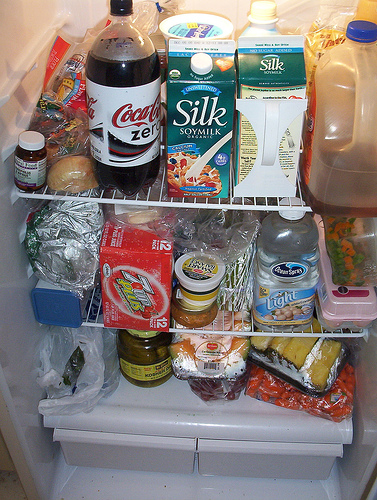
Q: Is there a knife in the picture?
A: No, there are no knives.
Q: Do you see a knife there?
A: No, there are no knives.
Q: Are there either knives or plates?
A: No, there are no knives or plates.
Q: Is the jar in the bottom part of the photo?
A: Yes, the jar is in the bottom of the image.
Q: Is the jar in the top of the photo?
A: No, the jar is in the bottom of the image.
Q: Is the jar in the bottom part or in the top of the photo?
A: The jar is in the bottom of the image.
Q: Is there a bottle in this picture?
A: Yes, there is a bottle.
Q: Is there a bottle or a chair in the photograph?
A: Yes, there is a bottle.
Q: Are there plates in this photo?
A: No, there are no plates.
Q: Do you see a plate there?
A: No, there are no plates.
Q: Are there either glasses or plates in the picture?
A: No, there are no plates or glasses.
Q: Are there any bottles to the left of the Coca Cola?
A: Yes, there is a bottle to the left of the Coca Cola.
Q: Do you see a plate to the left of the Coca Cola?
A: No, there is a bottle to the left of the Coca Cola.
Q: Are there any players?
A: No, there are no players.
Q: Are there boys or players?
A: No, there are no players or boys.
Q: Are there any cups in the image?
A: No, there are no cups.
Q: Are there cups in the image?
A: No, there are no cups.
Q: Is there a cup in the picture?
A: No, there are no cups.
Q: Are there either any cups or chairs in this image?
A: No, there are no cups or chairs.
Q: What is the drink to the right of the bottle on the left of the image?
A: The drink is Coke.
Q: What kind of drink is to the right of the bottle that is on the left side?
A: The drink is Coke.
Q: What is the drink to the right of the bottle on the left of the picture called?
A: The drink is Coke.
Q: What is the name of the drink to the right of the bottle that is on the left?
A: The drink is Coke.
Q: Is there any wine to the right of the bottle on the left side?
A: No, there is Coke to the right of the bottle.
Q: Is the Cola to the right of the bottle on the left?
A: Yes, the Cola is to the right of the bottle.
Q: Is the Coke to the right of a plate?
A: No, the Coke is to the right of the bottle.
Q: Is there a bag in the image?
A: Yes, there is a bag.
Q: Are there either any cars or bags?
A: Yes, there is a bag.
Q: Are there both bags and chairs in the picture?
A: No, there is a bag but no chairs.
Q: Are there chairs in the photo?
A: No, there are no chairs.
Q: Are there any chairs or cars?
A: No, there are no chairs or cars.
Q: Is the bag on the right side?
A: Yes, the bag is on the right of the image.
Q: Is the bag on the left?
A: No, the bag is on the right of the image.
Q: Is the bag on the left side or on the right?
A: The bag is on the right of the image.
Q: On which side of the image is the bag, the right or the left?
A: The bag is on the right of the image.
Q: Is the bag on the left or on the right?
A: The bag is on the right of the image.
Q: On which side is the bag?
A: The bag is on the right of the image.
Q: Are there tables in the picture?
A: No, there are no tables.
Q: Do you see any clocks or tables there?
A: No, there are no tables or clocks.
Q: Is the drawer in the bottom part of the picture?
A: Yes, the drawer is in the bottom of the image.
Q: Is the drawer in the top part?
A: No, the drawer is in the bottom of the image.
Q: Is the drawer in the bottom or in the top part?
A: The drawer is in the bottom of the image.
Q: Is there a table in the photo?
A: No, there are no tables.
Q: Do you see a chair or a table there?
A: No, there are no tables or chairs.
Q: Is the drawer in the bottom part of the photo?
A: Yes, the drawer is in the bottom of the image.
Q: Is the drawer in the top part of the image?
A: No, the drawer is in the bottom of the image.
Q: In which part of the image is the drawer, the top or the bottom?
A: The drawer is in the bottom of the image.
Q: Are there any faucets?
A: No, there are no faucets.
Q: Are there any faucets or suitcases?
A: No, there are no faucets or suitcases.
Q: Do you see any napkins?
A: No, there are no napkins.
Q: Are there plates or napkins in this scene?
A: No, there are no napkins or plates.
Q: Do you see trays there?
A: No, there are no trays.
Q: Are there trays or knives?
A: No, there are no trays or knives.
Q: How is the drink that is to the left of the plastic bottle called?
A: The drink is juice.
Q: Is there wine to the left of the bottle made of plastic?
A: No, there is juice to the left of the bottle.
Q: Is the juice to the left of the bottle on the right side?
A: Yes, the juice is to the left of the bottle.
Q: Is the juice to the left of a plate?
A: No, the juice is to the left of the bottle.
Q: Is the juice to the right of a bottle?
A: No, the juice is to the left of a bottle.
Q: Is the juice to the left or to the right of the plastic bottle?
A: The juice is to the left of the bottle.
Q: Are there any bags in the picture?
A: Yes, there is a bag.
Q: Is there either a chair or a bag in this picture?
A: Yes, there is a bag.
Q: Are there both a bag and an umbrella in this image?
A: No, there is a bag but no umbrellas.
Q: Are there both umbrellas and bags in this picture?
A: No, there is a bag but no umbrellas.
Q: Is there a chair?
A: No, there are no chairs.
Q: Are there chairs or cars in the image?
A: No, there are no chairs or cars.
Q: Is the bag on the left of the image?
A: No, the bag is on the right of the image.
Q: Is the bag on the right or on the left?
A: The bag is on the right of the image.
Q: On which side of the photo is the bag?
A: The bag is on the right of the image.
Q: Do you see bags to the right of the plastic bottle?
A: Yes, there is a bag to the right of the bottle.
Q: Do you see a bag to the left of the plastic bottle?
A: No, the bag is to the right of the bottle.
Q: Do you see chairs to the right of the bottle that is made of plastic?
A: No, there is a bag to the right of the bottle.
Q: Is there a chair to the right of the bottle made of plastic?
A: No, there is a bag to the right of the bottle.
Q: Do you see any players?
A: No, there are no players.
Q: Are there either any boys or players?
A: No, there are no players or boys.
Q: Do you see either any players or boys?
A: No, there are no players or boys.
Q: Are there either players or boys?
A: No, there are no players or boys.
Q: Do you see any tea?
A: Yes, there is tea.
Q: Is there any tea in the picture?
A: Yes, there is tea.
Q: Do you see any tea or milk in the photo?
A: Yes, there is tea.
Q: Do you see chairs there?
A: No, there are no chairs.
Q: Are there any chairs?
A: No, there are no chairs.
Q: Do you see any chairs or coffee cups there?
A: No, there are no chairs or coffee cups.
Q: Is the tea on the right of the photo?
A: Yes, the tea is on the right of the image.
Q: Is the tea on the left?
A: No, the tea is on the right of the image.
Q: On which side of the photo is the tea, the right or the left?
A: The tea is on the right of the image.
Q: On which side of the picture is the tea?
A: The tea is on the right of the image.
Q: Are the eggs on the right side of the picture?
A: Yes, the eggs are on the right of the image.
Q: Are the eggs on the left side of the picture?
A: No, the eggs are on the right of the image.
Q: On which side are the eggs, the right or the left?
A: The eggs are on the right of the image.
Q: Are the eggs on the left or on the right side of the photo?
A: The eggs are on the right of the image.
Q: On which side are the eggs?
A: The eggs are on the right of the image.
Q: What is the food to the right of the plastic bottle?
A: The food is eggs.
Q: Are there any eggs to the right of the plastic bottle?
A: Yes, there are eggs to the right of the bottle.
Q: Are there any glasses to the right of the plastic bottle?
A: No, there are eggs to the right of the bottle.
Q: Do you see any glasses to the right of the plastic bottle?
A: No, there are eggs to the right of the bottle.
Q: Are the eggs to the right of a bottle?
A: Yes, the eggs are to the right of a bottle.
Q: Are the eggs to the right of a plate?
A: No, the eggs are to the right of a bottle.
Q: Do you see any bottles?
A: Yes, there is a bottle.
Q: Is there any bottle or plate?
A: Yes, there is a bottle.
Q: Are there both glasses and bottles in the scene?
A: No, there is a bottle but no glasses.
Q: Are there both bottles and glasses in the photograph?
A: No, there is a bottle but no glasses.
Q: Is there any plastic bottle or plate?
A: Yes, there is a plastic bottle.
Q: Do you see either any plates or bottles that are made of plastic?
A: Yes, the bottle is made of plastic.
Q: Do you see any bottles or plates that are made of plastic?
A: Yes, the bottle is made of plastic.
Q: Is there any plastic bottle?
A: Yes, there is a bottle that is made of plastic.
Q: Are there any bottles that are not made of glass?
A: Yes, there is a bottle that is made of plastic.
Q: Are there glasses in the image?
A: No, there are no glasses.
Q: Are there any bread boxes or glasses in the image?
A: No, there are no glasses or bread boxes.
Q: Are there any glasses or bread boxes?
A: No, there are no glasses or bread boxes.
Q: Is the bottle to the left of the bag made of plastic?
A: Yes, the bottle is made of plastic.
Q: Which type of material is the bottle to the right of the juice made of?
A: The bottle is made of plastic.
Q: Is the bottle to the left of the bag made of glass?
A: No, the bottle is made of plastic.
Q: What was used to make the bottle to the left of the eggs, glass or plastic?
A: The bottle is made of plastic.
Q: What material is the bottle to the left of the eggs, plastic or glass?
A: The bottle is made of plastic.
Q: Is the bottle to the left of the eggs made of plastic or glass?
A: The bottle is made of plastic.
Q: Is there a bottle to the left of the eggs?
A: Yes, there is a bottle to the left of the eggs.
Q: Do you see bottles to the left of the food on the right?
A: Yes, there is a bottle to the left of the eggs.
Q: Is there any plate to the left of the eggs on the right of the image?
A: No, there is a bottle to the left of the eggs.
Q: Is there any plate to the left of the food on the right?
A: No, there is a bottle to the left of the eggs.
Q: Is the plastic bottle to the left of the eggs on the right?
A: Yes, the bottle is to the left of the eggs.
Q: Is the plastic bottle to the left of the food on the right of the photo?
A: Yes, the bottle is to the left of the eggs.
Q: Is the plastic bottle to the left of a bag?
A: Yes, the bottle is to the left of a bag.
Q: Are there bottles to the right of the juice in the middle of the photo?
A: Yes, there is a bottle to the right of the juice.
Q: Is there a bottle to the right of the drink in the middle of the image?
A: Yes, there is a bottle to the right of the juice.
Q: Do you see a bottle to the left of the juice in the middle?
A: No, the bottle is to the right of the juice.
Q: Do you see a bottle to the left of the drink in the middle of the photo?
A: No, the bottle is to the right of the juice.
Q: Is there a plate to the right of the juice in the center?
A: No, there is a bottle to the right of the juice.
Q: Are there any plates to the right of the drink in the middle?
A: No, there is a bottle to the right of the juice.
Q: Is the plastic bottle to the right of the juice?
A: Yes, the bottle is to the right of the juice.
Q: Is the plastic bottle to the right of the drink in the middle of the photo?
A: Yes, the bottle is to the right of the juice.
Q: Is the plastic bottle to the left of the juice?
A: No, the bottle is to the right of the juice.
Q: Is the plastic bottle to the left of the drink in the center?
A: No, the bottle is to the right of the juice.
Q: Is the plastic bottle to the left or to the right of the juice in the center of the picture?
A: The bottle is to the right of the juice.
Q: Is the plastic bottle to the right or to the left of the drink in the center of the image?
A: The bottle is to the right of the juice.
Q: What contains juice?
A: The bottle contains juice.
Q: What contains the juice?
A: The bottle contains juice.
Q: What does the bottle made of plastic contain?
A: The bottle contains juice.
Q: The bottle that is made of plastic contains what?
A: The bottle contains juice.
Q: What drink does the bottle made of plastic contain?
A: The bottle contains juice.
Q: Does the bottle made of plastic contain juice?
A: Yes, the bottle contains juice.